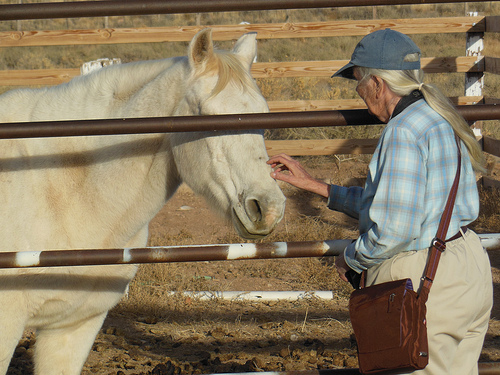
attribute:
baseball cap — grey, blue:
[330, 26, 419, 79]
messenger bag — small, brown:
[348, 130, 464, 375]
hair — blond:
[193, 43, 257, 100]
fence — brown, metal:
[0, 105, 499, 278]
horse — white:
[0, 26, 286, 374]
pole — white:
[171, 290, 333, 299]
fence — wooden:
[1, 11, 499, 189]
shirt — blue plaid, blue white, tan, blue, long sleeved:
[320, 89, 479, 270]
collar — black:
[390, 88, 422, 116]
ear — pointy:
[188, 24, 215, 68]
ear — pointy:
[232, 31, 260, 68]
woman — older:
[264, 28, 495, 374]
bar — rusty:
[0, 232, 499, 270]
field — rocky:
[2, 0, 499, 374]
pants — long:
[367, 225, 492, 374]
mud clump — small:
[242, 353, 264, 369]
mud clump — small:
[152, 360, 177, 374]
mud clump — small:
[331, 350, 357, 367]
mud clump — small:
[209, 324, 229, 340]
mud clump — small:
[277, 346, 298, 359]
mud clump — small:
[257, 318, 297, 331]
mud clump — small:
[211, 356, 234, 374]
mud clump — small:
[112, 337, 146, 359]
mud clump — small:
[142, 315, 158, 324]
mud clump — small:
[173, 332, 200, 344]